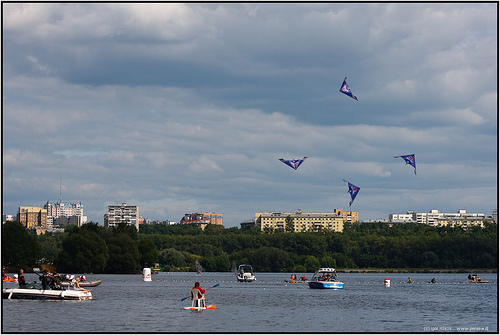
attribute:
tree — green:
[62, 226, 112, 271]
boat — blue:
[307, 266, 343, 288]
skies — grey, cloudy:
[21, 22, 480, 170]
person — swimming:
[405, 274, 414, 286]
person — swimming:
[188, 276, 205, 300]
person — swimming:
[423, 275, 443, 284]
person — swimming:
[278, 268, 303, 289]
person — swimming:
[69, 273, 89, 295]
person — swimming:
[465, 267, 483, 283]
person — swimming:
[16, 267, 25, 286]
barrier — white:
[374, 267, 411, 294]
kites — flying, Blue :
[279, 76, 416, 205]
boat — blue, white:
[305, 267, 342, 291]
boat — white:
[300, 260, 349, 305]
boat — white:
[234, 262, 267, 288]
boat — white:
[0, 287, 97, 307]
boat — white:
[34, 261, 105, 288]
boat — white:
[182, 297, 217, 322]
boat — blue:
[293, 253, 352, 312]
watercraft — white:
[10, 285, 93, 302]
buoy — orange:
[382, 276, 392, 288]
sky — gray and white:
[42, 15, 243, 130]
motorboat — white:
[230, 261, 258, 283]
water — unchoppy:
[3, 270, 495, 330]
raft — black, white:
[14, 240, 125, 330]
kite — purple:
[334, 77, 359, 99]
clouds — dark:
[202, 43, 411, 141]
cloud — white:
[326, 119, 439, 148]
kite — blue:
[323, 172, 375, 214]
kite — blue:
[337, 75, 362, 102]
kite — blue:
[394, 152, 415, 173]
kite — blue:
[279, 157, 310, 168]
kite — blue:
[344, 179, 364, 209]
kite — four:
[389, 147, 419, 182]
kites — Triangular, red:
[392, 151, 416, 171]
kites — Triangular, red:
[338, 71, 358, 102]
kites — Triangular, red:
[344, 173, 362, 208]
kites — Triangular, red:
[277, 150, 310, 171]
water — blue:
[98, 300, 179, 329]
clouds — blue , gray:
[6, 5, 494, 215]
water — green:
[238, 285, 310, 329]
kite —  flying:
[335, 177, 362, 207]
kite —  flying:
[278, 155, 305, 172]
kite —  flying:
[393, 152, 418, 176]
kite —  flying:
[336, 74, 360, 102]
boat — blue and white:
[307, 268, 348, 290]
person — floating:
[171, 268, 226, 318]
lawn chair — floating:
[188, 286, 206, 312]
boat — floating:
[0, 266, 94, 301]